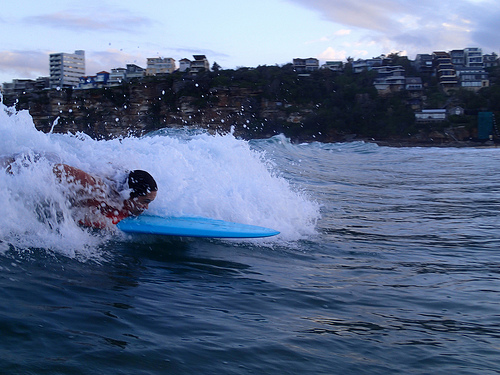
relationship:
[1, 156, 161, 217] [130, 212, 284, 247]
surfer laying on top of surfboard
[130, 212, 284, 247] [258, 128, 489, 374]
surfboard in water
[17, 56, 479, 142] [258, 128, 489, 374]
city behind water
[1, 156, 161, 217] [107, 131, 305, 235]
surfer surrounded by waves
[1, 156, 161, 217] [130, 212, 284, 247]
surfer on top of surfboard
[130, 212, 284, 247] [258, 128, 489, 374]
surfboard on top of water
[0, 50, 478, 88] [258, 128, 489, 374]
buildings are behind water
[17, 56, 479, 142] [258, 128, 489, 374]
city next to water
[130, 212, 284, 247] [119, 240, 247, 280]
surfboard has shadow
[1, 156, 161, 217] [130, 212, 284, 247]
surfer in middle of surfboard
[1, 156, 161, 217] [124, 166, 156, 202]
surfer has black hair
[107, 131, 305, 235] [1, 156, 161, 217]
waves are splashing on surfer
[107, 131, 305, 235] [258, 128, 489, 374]
waves are splashing in water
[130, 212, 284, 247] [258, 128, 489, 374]
surfboard covered by water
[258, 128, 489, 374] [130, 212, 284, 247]
water underneath surfboard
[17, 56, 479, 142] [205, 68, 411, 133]
city has trees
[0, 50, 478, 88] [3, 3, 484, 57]
buildings are beneath skies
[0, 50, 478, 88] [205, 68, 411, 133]
buildings are on top of trees